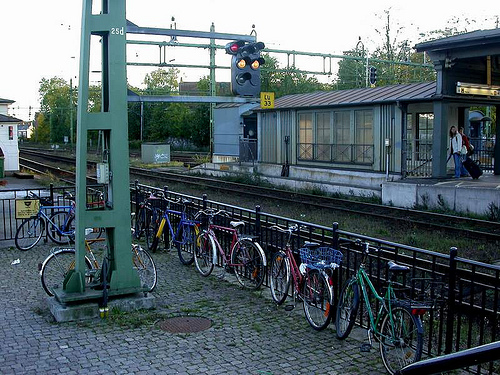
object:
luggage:
[462, 156, 484, 179]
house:
[0, 96, 27, 184]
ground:
[448, 150, 457, 166]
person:
[449, 125, 472, 178]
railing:
[135, 181, 500, 375]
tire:
[128, 245, 158, 292]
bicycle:
[151, 190, 201, 265]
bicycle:
[188, 206, 277, 296]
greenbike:
[335, 237, 424, 374]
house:
[242, 82, 470, 191]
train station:
[183, 27, 500, 360]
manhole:
[156, 313, 219, 332]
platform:
[0, 235, 457, 375]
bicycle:
[269, 224, 337, 331]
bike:
[38, 237, 158, 300]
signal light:
[224, 41, 265, 95]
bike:
[14, 197, 102, 252]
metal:
[52, 0, 140, 307]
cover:
[159, 316, 210, 334]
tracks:
[19, 140, 500, 368]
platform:
[380, 171, 499, 210]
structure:
[52, 0, 435, 306]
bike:
[268, 225, 343, 331]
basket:
[297, 247, 343, 270]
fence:
[0, 179, 500, 374]